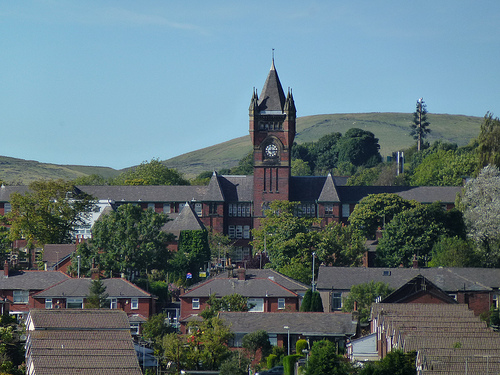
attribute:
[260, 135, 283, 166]
clock — small, black, large, white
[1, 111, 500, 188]
hills — flat, green, grassy, far, sloped, present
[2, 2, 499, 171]
sky — blue, cloudless, clear, bright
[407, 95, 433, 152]
tree — alone, standing, tall, white leaved, present, very tall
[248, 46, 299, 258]
clock tower — tall, brick, red brick, pointy, red, big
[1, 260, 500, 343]
houses — in a row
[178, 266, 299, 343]
house — brick, red, big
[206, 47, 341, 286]
building — brick, large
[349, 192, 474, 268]
trees — leafy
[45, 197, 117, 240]
building — white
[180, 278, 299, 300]
roof — black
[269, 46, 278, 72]
spire — pointed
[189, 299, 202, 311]
window — white, small